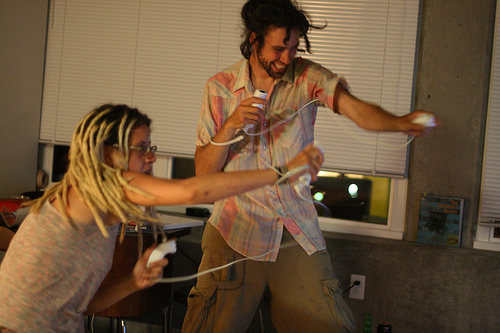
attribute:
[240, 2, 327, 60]
hair — black, long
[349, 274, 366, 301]
socket — white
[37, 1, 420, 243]
window — large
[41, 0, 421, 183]
blinds — white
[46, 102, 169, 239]
dreadlocks — blond, yellow, blonde, thick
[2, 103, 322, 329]
player — woman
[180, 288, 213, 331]
pocket — large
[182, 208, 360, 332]
pants — khaki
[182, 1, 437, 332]
man — young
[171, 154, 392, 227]
pane — glass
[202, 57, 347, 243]
shirt — plaid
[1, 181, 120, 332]
top — grey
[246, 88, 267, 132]
controller — white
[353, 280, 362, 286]
plug — black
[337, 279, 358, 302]
cable — small, black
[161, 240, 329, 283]
wire — thin, white